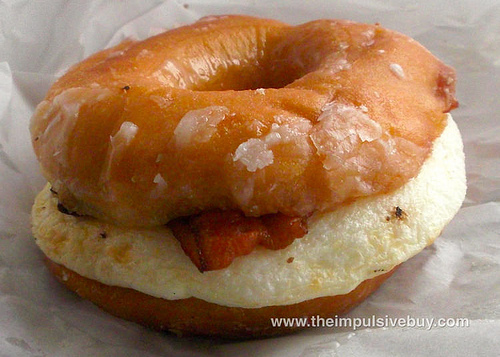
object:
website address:
[270, 315, 470, 332]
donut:
[28, 14, 459, 229]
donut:
[43, 257, 403, 340]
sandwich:
[28, 13, 467, 340]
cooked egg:
[30, 111, 467, 310]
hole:
[159, 32, 325, 97]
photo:
[0, 0, 500, 357]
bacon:
[166, 207, 309, 274]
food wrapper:
[0, 0, 499, 356]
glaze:
[224, 101, 427, 217]